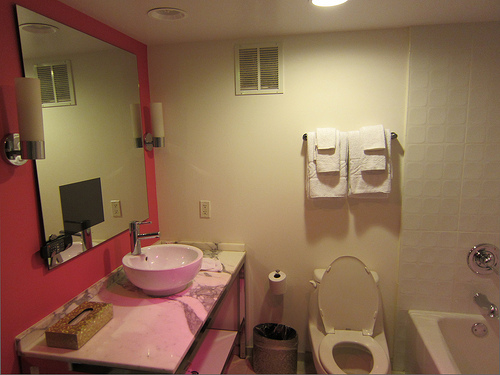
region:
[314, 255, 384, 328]
toilet seat is up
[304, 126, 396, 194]
towels are white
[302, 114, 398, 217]
six towels are on the wall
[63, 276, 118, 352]
box of tissue on the couter top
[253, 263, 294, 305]
toilet paper holder on the wall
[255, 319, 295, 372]
trash can under the toilet paper holder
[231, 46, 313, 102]
vent on the wall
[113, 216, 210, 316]
sink is on the counter top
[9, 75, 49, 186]
light on the wall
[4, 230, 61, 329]
wall is painted red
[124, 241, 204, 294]
white bowl sink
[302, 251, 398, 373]
white toilet next to the tub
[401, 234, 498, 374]
white tub with silver plumbing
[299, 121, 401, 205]
six white towels hanging on a towel bar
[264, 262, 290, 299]
toilet paper on a toilet paper bar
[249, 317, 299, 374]
brown and black trash can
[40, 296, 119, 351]
brown tissue box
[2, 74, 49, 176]
white and silver light on the wall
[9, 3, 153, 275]
large mirror hanging on the bathroom wall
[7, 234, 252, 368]
bathroom vanity with marble countertop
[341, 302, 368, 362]
A toilet bowl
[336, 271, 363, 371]
A toilet bowl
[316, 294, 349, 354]
A toilet bowl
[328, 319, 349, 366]
A toilet bowl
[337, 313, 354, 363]
A toilet bowl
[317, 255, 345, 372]
A toilet bowl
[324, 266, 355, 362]
A toilet bowl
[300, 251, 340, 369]
A toilet bowl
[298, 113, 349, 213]
Towels hanging in bathroom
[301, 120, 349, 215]
Towels on bar are white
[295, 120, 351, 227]
Three white towels in bathroom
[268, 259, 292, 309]
Tissue paper hanging in bathroom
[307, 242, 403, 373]
Bathroom toilet is white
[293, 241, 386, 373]
Lid on toilet is up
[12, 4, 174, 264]
Large mirror on bathroom wall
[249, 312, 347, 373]
Waste basket next to toilet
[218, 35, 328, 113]
Heat vent next to ceiling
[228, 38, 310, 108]
The heat vent is white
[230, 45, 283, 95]
The vent on the wall of the bathroom.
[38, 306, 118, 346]
The box of tissues on the counter.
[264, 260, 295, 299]
The roll of toilet paper above the trash can.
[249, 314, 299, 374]
The trash can next to the toilet.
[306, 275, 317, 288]
The handle to flush the toilet.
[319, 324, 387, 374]
The seat of the toilet.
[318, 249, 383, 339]
The toilet seat lid of the toilet.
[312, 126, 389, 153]
The smaller towels hanging up.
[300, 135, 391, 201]
The larger towels hanging up.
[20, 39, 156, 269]
The mirror hanging on the wall.